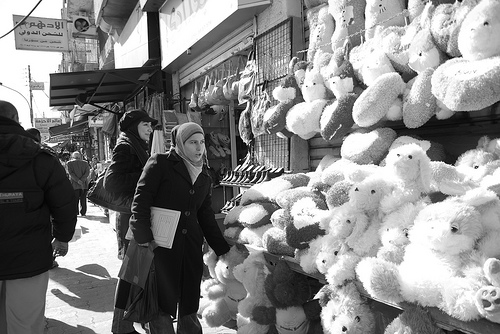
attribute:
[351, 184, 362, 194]
toy nose — black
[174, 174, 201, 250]
buttons — black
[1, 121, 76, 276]
coat — black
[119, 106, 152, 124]
hat — black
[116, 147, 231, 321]
coat — black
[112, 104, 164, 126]
hat — black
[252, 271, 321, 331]
bear — brown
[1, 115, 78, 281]
jacket — black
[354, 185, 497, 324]
teddy bear — white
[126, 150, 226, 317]
jacket — black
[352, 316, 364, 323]
eye — black